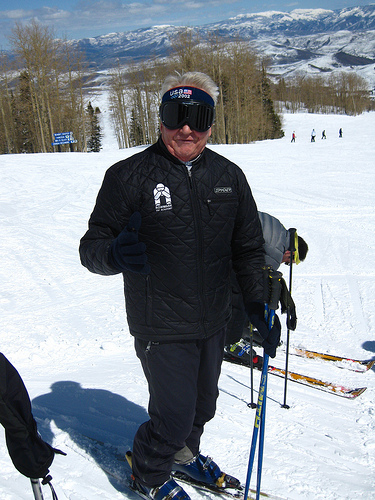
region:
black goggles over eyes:
[149, 100, 221, 133]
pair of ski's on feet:
[110, 433, 275, 498]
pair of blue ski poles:
[241, 264, 284, 497]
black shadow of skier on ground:
[10, 363, 276, 498]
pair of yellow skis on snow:
[214, 296, 372, 411]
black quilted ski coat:
[70, 134, 276, 348]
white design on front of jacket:
[140, 174, 180, 223]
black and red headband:
[155, 83, 220, 113]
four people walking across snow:
[285, 116, 352, 151]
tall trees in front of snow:
[1, 19, 289, 170]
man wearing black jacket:
[75, 133, 275, 370]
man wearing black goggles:
[158, 88, 220, 150]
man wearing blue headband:
[154, 80, 216, 116]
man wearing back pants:
[113, 315, 237, 497]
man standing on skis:
[81, 58, 307, 499]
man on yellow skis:
[210, 202, 358, 420]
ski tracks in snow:
[30, 294, 140, 492]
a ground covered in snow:
[54, 175, 374, 437]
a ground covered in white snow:
[9, 161, 326, 474]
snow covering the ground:
[6, 194, 307, 494]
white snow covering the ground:
[33, 158, 349, 423]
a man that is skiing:
[104, 60, 372, 393]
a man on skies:
[82, 93, 275, 429]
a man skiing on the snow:
[76, 106, 372, 407]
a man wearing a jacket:
[88, 57, 300, 308]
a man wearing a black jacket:
[88, 75, 308, 485]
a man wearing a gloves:
[124, 77, 368, 401]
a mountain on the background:
[2, 3, 370, 91]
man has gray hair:
[94, 61, 268, 221]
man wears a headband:
[114, 53, 251, 207]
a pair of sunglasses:
[153, 102, 218, 139]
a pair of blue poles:
[242, 258, 284, 498]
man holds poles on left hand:
[72, 60, 282, 498]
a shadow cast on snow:
[39, 358, 136, 493]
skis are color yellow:
[270, 337, 373, 407]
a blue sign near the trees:
[47, 123, 81, 154]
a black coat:
[69, 141, 275, 351]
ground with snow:
[309, 142, 369, 318]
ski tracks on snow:
[254, 150, 354, 197]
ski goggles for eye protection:
[160, 98, 214, 130]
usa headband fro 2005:
[157, 84, 213, 107]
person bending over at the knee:
[257, 209, 303, 271]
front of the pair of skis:
[291, 343, 373, 398]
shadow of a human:
[31, 380, 148, 419]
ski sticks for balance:
[242, 266, 280, 499]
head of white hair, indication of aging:
[154, 70, 220, 99]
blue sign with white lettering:
[51, 130, 76, 149]